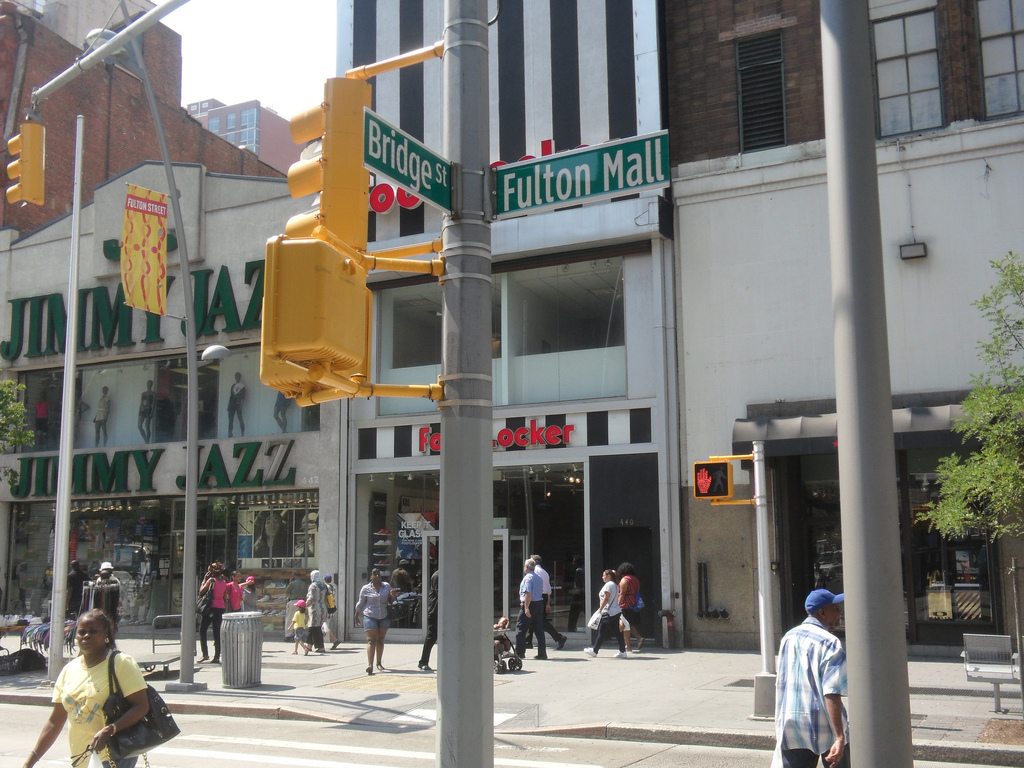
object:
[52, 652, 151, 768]
shirt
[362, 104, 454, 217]
sign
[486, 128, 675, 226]
sign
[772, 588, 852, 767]
man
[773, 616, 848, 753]
shirt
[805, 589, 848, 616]
cap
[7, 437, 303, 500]
sign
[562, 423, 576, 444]
letters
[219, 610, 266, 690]
can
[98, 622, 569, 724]
sidewalk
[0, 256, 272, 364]
sign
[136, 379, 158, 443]
one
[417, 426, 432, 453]
letter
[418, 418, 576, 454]
footlocker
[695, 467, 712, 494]
hand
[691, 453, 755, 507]
object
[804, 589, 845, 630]
head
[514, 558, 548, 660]
man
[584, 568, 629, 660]
woman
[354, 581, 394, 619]
shirt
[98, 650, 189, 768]
object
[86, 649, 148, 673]
shoulder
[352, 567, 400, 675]
people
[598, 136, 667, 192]
words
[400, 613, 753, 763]
ground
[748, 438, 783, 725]
pole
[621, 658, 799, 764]
street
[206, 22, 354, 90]
sky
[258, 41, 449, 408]
light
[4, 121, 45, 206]
light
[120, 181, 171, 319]
banner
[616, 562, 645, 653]
woman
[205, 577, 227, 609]
shirt